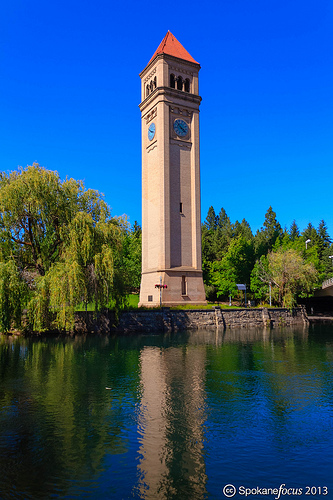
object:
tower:
[137, 30, 211, 307]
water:
[1, 318, 332, 498]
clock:
[173, 118, 191, 138]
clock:
[147, 123, 157, 142]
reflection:
[138, 347, 211, 499]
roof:
[137, 28, 201, 77]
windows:
[169, 74, 177, 91]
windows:
[151, 75, 157, 92]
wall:
[71, 306, 312, 335]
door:
[181, 275, 187, 299]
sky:
[0, 0, 331, 242]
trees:
[0, 163, 86, 334]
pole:
[303, 238, 311, 250]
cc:
[223, 483, 237, 496]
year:
[305, 485, 329, 496]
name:
[238, 482, 303, 498]